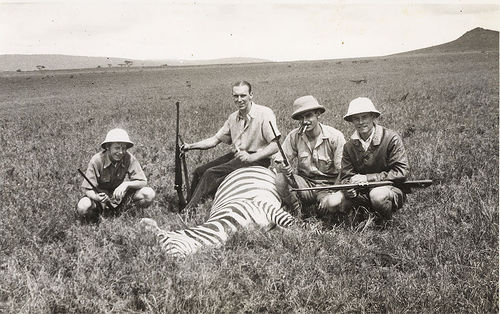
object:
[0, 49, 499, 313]
ground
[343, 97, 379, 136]
head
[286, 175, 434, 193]
gun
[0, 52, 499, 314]
field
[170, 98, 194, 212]
rifle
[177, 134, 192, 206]
sling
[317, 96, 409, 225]
man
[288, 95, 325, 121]
hat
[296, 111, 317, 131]
man's head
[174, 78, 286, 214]
man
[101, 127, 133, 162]
head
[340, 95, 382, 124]
hat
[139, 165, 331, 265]
zebra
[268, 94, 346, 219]
man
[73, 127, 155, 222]
man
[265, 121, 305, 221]
gun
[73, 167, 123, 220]
gun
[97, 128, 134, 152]
hat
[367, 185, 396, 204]
lap